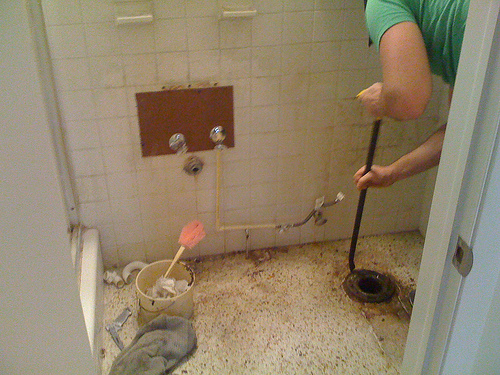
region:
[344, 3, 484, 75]
man has green shirt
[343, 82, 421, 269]
man has brown pole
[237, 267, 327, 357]
brown and white tile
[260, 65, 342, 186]
white tile on wall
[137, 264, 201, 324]
white bucket on floor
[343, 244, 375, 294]
grey drain in tub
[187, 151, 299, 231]
white pipe on wall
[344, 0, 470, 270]
Person holding a metal pipe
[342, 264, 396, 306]
Gross metal bathroom floor drain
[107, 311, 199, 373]
Gray rag on the floor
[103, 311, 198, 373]
Dirty grey towel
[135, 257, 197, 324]
Dirty white bucket with metal handle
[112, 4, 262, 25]
Two white bar soap holders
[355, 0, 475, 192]
Person wearing a green shirt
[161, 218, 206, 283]
Cleaning sponge on wood handle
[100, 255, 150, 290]
White plumbing tubes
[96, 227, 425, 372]
Dirty gross bathroom floor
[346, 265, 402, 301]
Rusty drain in floor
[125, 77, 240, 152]
Rusted metal square on wall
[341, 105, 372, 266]
Metal pry bar in man's hand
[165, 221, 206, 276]
Pink toilet brush in bucket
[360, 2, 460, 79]
Green shirt on man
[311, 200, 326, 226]
Water handle in bathroom wall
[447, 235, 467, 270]
Groove for tongue of door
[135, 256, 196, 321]
Tan bucket on bathroom floor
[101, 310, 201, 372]
Gray towel on floor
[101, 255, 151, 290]
White pvc pipe on floor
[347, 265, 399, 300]
hole in the bathroom floor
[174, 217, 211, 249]
pink toilet brush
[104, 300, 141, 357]
opened knife on the ground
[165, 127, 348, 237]
pipes coming out of the wall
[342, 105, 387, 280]
long metal pole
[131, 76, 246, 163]
brown square on the wall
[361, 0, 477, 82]
green short sleeved tee shirt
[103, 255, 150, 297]
white pipe on the ground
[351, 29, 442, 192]
fleshy arms of a person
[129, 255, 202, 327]
white bucket on the ground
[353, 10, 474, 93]
man has green shirt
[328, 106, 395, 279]
man holds pry bar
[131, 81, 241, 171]
brown panel on wall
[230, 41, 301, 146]
white tile on wall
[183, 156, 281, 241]
white pipe on wall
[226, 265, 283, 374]
brown and white floor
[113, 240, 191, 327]
white bucket on floor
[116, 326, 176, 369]
grey towel on floor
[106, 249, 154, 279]
white pipes on floor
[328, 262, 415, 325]
brown drain on floor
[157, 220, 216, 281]
a pink and white toilet brush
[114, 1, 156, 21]
a white bathroom soap dish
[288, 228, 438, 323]
hole in the room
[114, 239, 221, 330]
bucket in the room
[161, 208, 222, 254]
top of the brush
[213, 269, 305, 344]
ground in the room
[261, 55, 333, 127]
wall next to the lady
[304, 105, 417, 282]
bar in person's hand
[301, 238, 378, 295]
bottom of the pole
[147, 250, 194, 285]
handle of the brush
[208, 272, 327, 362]
many dots on ground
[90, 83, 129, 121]
white tile on the bathroom wall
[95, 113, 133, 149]
white tile on the bathroom wall